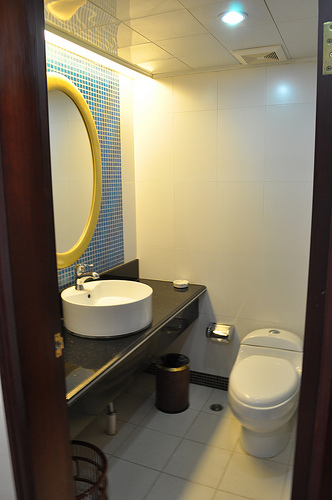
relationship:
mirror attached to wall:
[46, 71, 103, 267] [35, 33, 134, 291]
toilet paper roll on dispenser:
[212, 328, 226, 338] [205, 321, 234, 346]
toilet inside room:
[227, 324, 303, 458] [2, 8, 330, 499]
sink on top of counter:
[61, 280, 155, 340] [57, 284, 207, 397]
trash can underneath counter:
[155, 351, 191, 415] [57, 284, 207, 397]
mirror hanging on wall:
[46, 71, 103, 267] [35, 33, 134, 291]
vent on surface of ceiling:
[236, 42, 288, 73] [34, 3, 317, 68]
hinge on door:
[319, 20, 331, 79] [291, 2, 331, 499]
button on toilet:
[269, 327, 280, 337] [227, 324, 303, 458]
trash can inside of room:
[155, 351, 191, 415] [2, 8, 330, 499]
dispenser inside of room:
[205, 321, 234, 346] [2, 8, 330, 499]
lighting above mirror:
[40, 25, 155, 87] [46, 71, 103, 267]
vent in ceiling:
[236, 42, 288, 73] [34, 3, 317, 68]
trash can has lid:
[155, 351, 191, 415] [159, 352, 189, 370]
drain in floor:
[209, 402, 224, 416] [72, 367, 300, 499]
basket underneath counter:
[68, 437, 117, 499] [57, 284, 207, 397]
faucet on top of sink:
[74, 264, 101, 290] [61, 280, 155, 340]